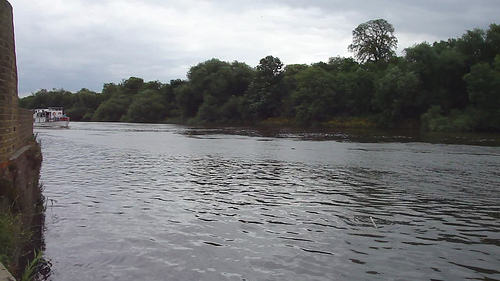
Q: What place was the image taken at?
A: It was taken at the river.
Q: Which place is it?
A: It is a river.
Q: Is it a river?
A: Yes, it is a river.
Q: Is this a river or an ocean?
A: It is a river.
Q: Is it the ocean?
A: No, it is the river.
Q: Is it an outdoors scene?
A: Yes, it is outdoors.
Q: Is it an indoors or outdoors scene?
A: It is outdoors.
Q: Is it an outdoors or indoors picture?
A: It is outdoors.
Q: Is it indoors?
A: No, it is outdoors.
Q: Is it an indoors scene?
A: No, it is outdoors.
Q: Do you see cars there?
A: No, there are no cars.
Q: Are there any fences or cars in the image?
A: No, there are no cars or fences.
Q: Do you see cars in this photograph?
A: No, there are no cars.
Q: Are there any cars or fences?
A: No, there are no cars or fences.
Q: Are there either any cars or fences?
A: No, there are no cars or fences.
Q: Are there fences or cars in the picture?
A: No, there are no cars or fences.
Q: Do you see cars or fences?
A: No, there are no cars or fences.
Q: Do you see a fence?
A: No, there are no fences.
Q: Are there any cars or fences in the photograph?
A: No, there are no fences or cars.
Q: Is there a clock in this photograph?
A: No, there are no clocks.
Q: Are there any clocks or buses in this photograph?
A: No, there are no clocks or buses.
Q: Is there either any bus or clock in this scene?
A: No, there are no clocks or buses.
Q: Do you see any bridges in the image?
A: No, there are no bridges.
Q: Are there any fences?
A: No, there are no fences.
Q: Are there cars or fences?
A: No, there are no fences or cars.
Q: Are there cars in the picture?
A: No, there are no cars.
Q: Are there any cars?
A: No, there are no cars.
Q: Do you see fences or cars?
A: No, there are no cars or fences.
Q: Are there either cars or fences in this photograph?
A: No, there are no cars or fences.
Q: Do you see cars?
A: No, there are no cars.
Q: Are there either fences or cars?
A: No, there are no cars or fences.